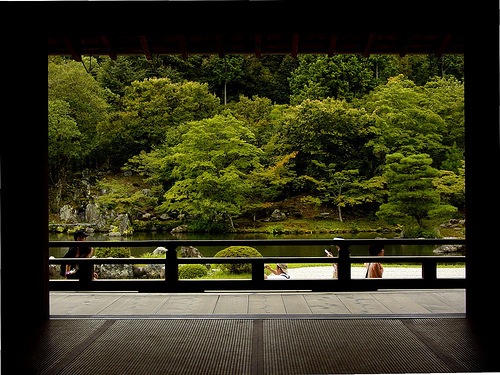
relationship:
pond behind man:
[19, 226, 473, 265] [326, 236, 344, 280]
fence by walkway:
[50, 239, 476, 296] [47, 289, 467, 319]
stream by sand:
[19, 226, 473, 265] [267, 265, 469, 281]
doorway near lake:
[41, 44, 472, 324] [48, 236, 465, 256]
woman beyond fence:
[363, 242, 386, 281] [50, 239, 476, 296]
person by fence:
[265, 264, 291, 283] [50, 239, 476, 296]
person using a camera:
[265, 264, 291, 283] [265, 263, 269, 270]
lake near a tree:
[19, 226, 473, 265] [122, 109, 297, 235]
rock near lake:
[113, 214, 134, 234] [19, 226, 473, 265]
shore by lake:
[50, 198, 470, 236] [19, 226, 473, 265]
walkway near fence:
[47, 289, 467, 319] [50, 239, 476, 296]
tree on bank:
[122, 109, 297, 235] [50, 198, 470, 236]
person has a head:
[265, 264, 291, 283] [276, 263, 287, 276]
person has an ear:
[61, 224, 87, 277] [74, 236, 79, 243]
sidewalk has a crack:
[47, 289, 467, 319] [245, 294, 253, 317]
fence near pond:
[50, 239, 476, 296] [49, 231, 463, 266]